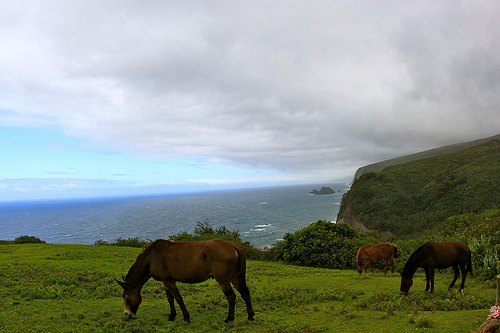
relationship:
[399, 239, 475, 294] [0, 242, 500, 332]
horse grazing on grass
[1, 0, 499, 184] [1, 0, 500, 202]
cloud floating in sky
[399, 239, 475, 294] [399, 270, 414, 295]
horse has head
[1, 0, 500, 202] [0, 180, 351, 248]
sky next to water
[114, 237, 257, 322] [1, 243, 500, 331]
horse grazing in field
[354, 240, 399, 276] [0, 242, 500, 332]
horse eating grass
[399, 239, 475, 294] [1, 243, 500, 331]
horse grazing in field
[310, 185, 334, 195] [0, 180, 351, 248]
boulder jutting out water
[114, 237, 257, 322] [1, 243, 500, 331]
horse standing in field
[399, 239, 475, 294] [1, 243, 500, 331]
horse eating in field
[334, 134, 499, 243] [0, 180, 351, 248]
cliff next to water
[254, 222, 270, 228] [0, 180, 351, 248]
cap in middle of water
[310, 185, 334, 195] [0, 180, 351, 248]
boulder formed in water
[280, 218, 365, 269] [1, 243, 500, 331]
bush growing on field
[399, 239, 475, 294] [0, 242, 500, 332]
horse eating grass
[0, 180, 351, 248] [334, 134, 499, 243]
water next to cliff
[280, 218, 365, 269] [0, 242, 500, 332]
bush growing in grass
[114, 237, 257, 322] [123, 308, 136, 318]
horse has mouth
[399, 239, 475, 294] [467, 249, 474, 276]
horse has tail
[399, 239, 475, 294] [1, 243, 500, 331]
horse standing in field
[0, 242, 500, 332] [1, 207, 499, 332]
grass on top of hill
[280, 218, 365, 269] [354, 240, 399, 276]
bush behind horse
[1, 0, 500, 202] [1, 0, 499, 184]
sky has cloud